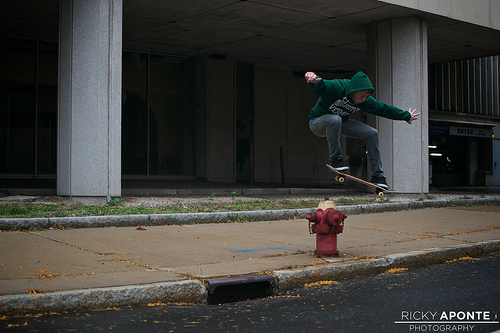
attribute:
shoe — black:
[328, 152, 351, 172]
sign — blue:
[451, 122, 496, 141]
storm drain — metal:
[201, 270, 280, 307]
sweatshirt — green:
[309, 80, 399, 141]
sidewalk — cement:
[11, 210, 493, 272]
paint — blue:
[227, 239, 294, 254]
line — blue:
[217, 230, 335, 285]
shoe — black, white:
[377, 180, 389, 189]